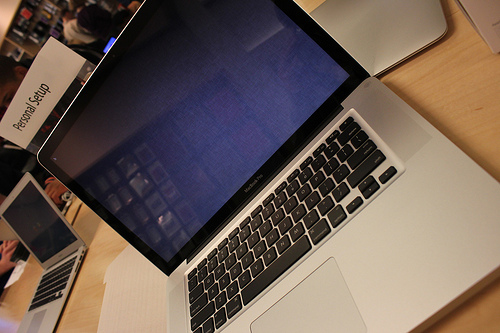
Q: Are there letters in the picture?
A: Yes, there are letters.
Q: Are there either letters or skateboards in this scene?
A: Yes, there are letters.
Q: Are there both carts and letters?
A: No, there are letters but no carts.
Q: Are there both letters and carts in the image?
A: No, there are letters but no carts.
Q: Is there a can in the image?
A: No, there are no cans.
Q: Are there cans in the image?
A: No, there are no cans.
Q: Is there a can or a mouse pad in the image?
A: No, there are no cans or mouse pads.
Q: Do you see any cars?
A: No, there are no cars.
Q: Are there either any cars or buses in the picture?
A: No, there are no cars or buses.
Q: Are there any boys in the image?
A: No, there are no boys.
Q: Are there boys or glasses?
A: No, there are no boys or glasses.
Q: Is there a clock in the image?
A: No, there are no clocks.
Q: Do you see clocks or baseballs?
A: No, there are no clocks or baseballs.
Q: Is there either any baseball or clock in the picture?
A: No, there are no clocks or baseballs.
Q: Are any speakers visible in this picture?
A: Yes, there is a speaker.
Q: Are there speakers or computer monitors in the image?
A: Yes, there is a speaker.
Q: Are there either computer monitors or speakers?
A: Yes, there is a speaker.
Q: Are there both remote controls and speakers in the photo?
A: No, there is a speaker but no remote controls.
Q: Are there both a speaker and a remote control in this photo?
A: No, there is a speaker but no remote controls.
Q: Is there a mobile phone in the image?
A: No, there are no cell phones.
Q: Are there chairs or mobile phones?
A: No, there are no mobile phones or chairs.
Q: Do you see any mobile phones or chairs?
A: No, there are no mobile phones or chairs.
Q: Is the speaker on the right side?
A: Yes, the speaker is on the right of the image.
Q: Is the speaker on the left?
A: No, the speaker is on the right of the image.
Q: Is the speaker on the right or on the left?
A: The speaker is on the right of the image.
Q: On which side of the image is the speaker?
A: The speaker is on the right of the image.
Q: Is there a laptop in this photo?
A: Yes, there is a laptop.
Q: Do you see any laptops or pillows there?
A: Yes, there is a laptop.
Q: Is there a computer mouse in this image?
A: No, there are no computer mice.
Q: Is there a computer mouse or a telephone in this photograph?
A: No, there are no computer mice or phones.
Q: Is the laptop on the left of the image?
A: Yes, the laptop is on the left of the image.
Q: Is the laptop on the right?
A: No, the laptop is on the left of the image.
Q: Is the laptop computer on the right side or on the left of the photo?
A: The laptop computer is on the left of the image.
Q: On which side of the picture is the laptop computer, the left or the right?
A: The laptop computer is on the left of the image.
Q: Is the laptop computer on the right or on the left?
A: The laptop computer is on the left of the image.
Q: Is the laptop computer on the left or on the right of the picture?
A: The laptop computer is on the left of the image.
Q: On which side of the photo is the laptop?
A: The laptop is on the left of the image.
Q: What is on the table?
A: The laptop is on the table.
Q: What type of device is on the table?
A: The device is a laptop.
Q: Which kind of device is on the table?
A: The device is a laptop.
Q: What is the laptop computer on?
A: The laptop computer is on the table.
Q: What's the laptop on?
A: The laptop computer is on the table.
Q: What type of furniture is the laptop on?
A: The laptop is on the table.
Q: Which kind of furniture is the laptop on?
A: The laptop is on the table.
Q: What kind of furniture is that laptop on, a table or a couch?
A: The laptop is on a table.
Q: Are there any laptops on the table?
A: Yes, there is a laptop on the table.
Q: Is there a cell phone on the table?
A: No, there is a laptop on the table.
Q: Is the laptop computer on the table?
A: Yes, the laptop computer is on the table.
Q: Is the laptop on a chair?
A: No, the laptop is on the table.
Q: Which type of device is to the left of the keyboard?
A: The device is a laptop.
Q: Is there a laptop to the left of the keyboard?
A: Yes, there is a laptop to the left of the keyboard.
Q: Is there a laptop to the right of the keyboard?
A: No, the laptop is to the left of the keyboard.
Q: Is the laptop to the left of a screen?
A: No, the laptop is to the left of the keyboard.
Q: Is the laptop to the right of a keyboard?
A: No, the laptop is to the left of a keyboard.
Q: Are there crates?
A: No, there are no crates.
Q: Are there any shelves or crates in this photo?
A: No, there are no crates or shelves.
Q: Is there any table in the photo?
A: Yes, there is a table.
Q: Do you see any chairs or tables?
A: Yes, there is a table.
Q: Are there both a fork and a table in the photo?
A: No, there is a table but no forks.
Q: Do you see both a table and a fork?
A: No, there is a table but no forks.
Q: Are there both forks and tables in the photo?
A: No, there is a table but no forks.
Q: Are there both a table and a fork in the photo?
A: No, there is a table but no forks.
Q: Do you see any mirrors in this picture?
A: No, there are no mirrors.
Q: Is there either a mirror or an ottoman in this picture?
A: No, there are no mirrors or ottomen.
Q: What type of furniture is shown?
A: The furniture is a table.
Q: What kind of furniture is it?
A: The piece of furniture is a table.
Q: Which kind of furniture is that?
A: This is a table.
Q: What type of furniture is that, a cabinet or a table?
A: This is a table.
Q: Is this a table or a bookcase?
A: This is a table.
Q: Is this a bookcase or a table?
A: This is a table.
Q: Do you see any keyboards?
A: Yes, there is a keyboard.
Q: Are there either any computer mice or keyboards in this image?
A: Yes, there is a keyboard.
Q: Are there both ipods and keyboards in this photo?
A: No, there is a keyboard but no ipods.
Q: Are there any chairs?
A: No, there are no chairs.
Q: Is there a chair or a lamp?
A: No, there are no chairs or lamps.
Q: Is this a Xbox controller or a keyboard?
A: This is a keyboard.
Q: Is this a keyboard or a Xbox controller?
A: This is a keyboard.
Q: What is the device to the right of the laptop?
A: The device is a keyboard.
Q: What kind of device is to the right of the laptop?
A: The device is a keyboard.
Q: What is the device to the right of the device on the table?
A: The device is a keyboard.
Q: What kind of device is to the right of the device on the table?
A: The device is a keyboard.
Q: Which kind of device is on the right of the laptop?
A: The device is a keyboard.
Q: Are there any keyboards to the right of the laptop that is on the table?
A: Yes, there is a keyboard to the right of the laptop.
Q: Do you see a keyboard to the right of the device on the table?
A: Yes, there is a keyboard to the right of the laptop.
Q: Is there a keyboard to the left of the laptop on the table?
A: No, the keyboard is to the right of the laptop.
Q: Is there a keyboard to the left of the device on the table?
A: No, the keyboard is to the right of the laptop.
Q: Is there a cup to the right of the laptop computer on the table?
A: No, there is a keyboard to the right of the laptop.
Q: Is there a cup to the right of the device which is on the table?
A: No, there is a keyboard to the right of the laptop.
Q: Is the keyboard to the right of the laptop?
A: Yes, the keyboard is to the right of the laptop.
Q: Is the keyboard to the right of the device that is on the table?
A: Yes, the keyboard is to the right of the laptop.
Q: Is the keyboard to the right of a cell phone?
A: No, the keyboard is to the right of the laptop.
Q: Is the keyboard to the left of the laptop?
A: No, the keyboard is to the right of the laptop.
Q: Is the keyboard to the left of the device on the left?
A: No, the keyboard is to the right of the laptop.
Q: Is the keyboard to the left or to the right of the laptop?
A: The keyboard is to the right of the laptop.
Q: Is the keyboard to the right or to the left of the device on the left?
A: The keyboard is to the right of the laptop.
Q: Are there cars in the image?
A: No, there are no cars.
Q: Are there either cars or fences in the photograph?
A: No, there are no cars or fences.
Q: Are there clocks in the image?
A: No, there are no clocks.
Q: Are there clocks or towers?
A: No, there are no clocks or towers.